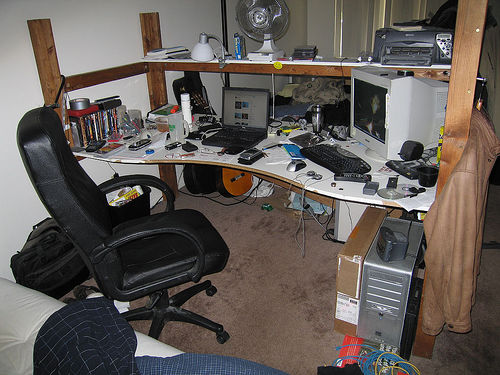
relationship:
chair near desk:
[17, 109, 231, 346] [76, 103, 440, 205]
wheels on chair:
[201, 281, 231, 346] [17, 109, 231, 346]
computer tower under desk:
[359, 218, 425, 360] [76, 103, 440, 205]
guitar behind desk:
[175, 77, 253, 198] [76, 103, 440, 205]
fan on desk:
[235, 5, 289, 59] [76, 103, 440, 205]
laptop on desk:
[204, 88, 273, 151] [76, 103, 440, 205]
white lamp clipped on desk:
[190, 32, 231, 70] [76, 103, 440, 205]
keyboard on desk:
[300, 139, 369, 178] [76, 103, 440, 205]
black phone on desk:
[172, 74, 219, 127] [76, 103, 440, 205]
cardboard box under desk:
[333, 205, 399, 339] [76, 103, 440, 205]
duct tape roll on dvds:
[69, 96, 92, 108] [69, 105, 144, 151]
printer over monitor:
[371, 19, 457, 63] [349, 68, 442, 155]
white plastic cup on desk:
[171, 111, 193, 143] [76, 103, 440, 205]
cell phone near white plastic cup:
[166, 133, 184, 152] [171, 111, 193, 143]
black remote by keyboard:
[335, 169, 373, 182] [300, 139, 369, 178]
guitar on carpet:
[175, 77, 253, 198] [134, 197, 493, 370]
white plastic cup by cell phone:
[171, 111, 193, 143] [166, 133, 184, 152]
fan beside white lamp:
[235, 5, 289, 59] [190, 32, 231, 70]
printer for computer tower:
[371, 19, 457, 63] [359, 218, 425, 360]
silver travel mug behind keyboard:
[309, 105, 321, 135] [300, 139, 369, 178]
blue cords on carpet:
[334, 351, 432, 372] [134, 197, 493, 370]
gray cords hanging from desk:
[281, 176, 329, 260] [76, 103, 440, 205]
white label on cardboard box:
[334, 290, 357, 326] [333, 205, 399, 339]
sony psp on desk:
[130, 135, 150, 154] [76, 103, 440, 205]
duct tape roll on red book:
[69, 96, 92, 108] [68, 108, 103, 118]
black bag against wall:
[10, 212, 93, 301] [8, 7, 220, 292]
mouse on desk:
[286, 161, 308, 174] [76, 103, 440, 205]